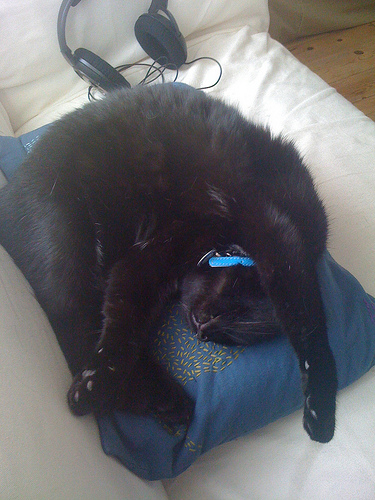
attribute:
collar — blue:
[197, 247, 261, 268]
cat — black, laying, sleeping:
[4, 90, 337, 444]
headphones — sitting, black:
[57, 0, 225, 94]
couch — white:
[2, 7, 373, 497]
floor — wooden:
[270, 2, 371, 122]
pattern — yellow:
[142, 293, 271, 452]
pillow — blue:
[2, 84, 375, 483]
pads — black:
[81, 363, 101, 384]